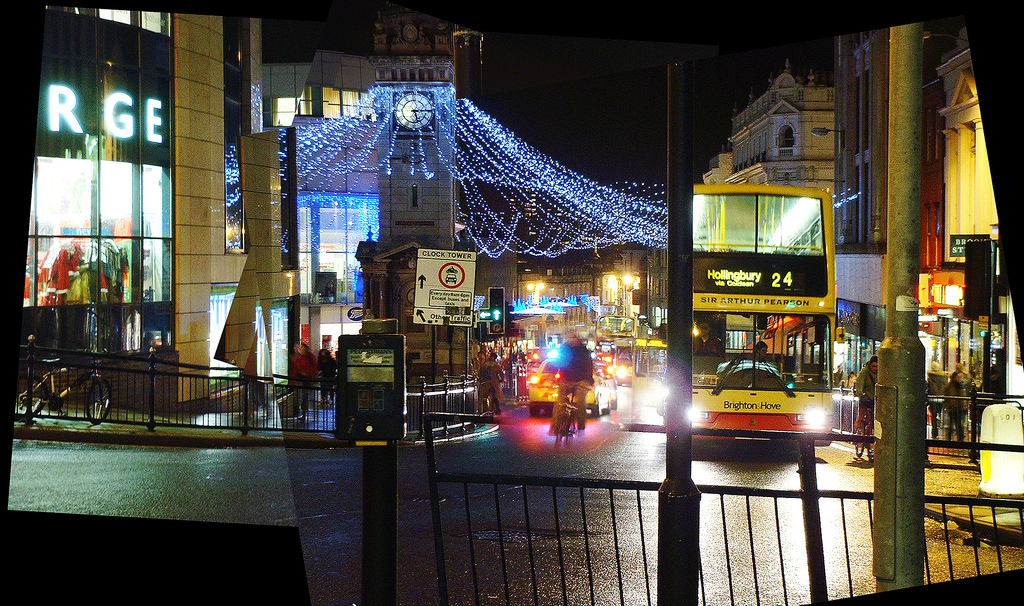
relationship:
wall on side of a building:
[731, 130, 762, 165] [707, 57, 841, 178]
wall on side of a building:
[377, 65, 458, 254] [252, 7, 486, 334]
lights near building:
[224, 80, 667, 268] [273, 13, 472, 318]